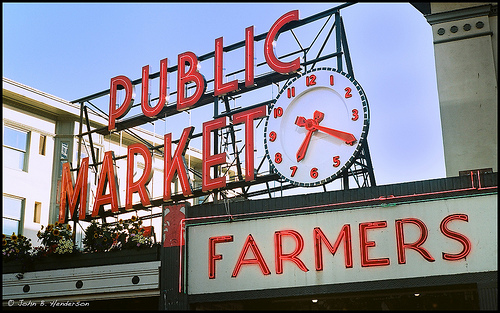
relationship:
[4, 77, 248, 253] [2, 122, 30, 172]
building has a window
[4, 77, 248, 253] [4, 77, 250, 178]
building has a roof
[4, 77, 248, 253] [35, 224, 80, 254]
building has bushes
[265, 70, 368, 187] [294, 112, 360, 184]
clock says seven twenty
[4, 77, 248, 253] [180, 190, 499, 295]
building has a sign